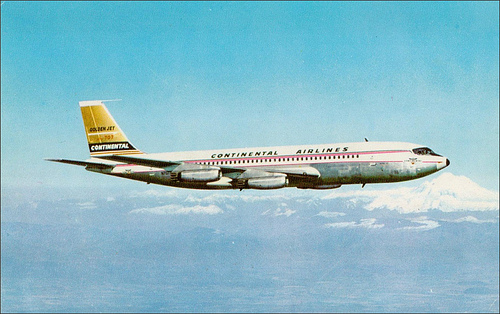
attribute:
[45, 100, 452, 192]
boeing — midair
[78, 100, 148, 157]
tail — gold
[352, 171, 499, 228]
mountain — covered, below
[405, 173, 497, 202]
snow — white, tall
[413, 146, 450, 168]
cockpit — black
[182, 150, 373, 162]
cabin — white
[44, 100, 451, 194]
jet — white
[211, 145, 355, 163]
writing — black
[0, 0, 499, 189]
sky — blue, hazy, cloudy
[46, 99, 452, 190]
airplane — large, continental airlines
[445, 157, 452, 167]
nose — black